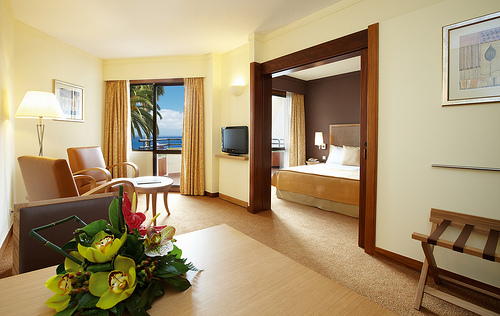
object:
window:
[131, 85, 182, 156]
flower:
[77, 229, 123, 264]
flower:
[88, 255, 136, 309]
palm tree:
[129, 82, 163, 137]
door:
[130, 84, 186, 176]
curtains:
[179, 78, 206, 196]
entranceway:
[249, 33, 379, 246]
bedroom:
[267, 77, 358, 217]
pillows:
[323, 144, 360, 166]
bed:
[271, 157, 360, 216]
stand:
[409, 208, 500, 315]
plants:
[30, 186, 193, 316]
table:
[166, 266, 366, 315]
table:
[128, 172, 174, 216]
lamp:
[14, 92, 67, 158]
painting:
[52, 81, 83, 124]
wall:
[0, 16, 105, 193]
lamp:
[312, 131, 327, 149]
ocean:
[133, 137, 185, 150]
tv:
[214, 126, 248, 158]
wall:
[206, 53, 251, 210]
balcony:
[140, 139, 182, 154]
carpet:
[133, 193, 483, 314]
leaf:
[482, 45, 495, 62]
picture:
[437, 12, 498, 106]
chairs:
[68, 142, 137, 177]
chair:
[20, 156, 86, 199]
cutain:
[102, 81, 129, 181]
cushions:
[68, 143, 113, 187]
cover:
[289, 161, 358, 185]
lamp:
[231, 74, 247, 89]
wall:
[373, 0, 498, 292]